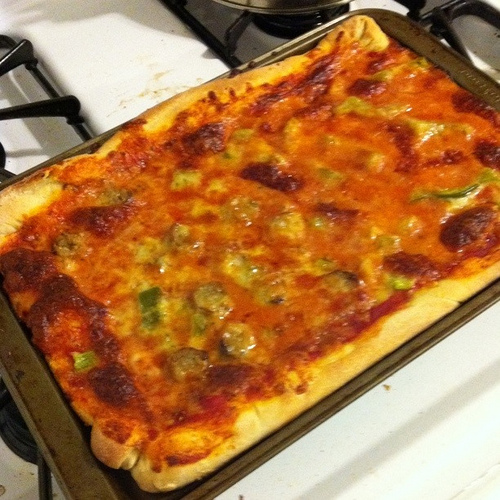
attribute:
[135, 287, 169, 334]
pepper — green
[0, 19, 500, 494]
pizza — big, rectangular, cheesy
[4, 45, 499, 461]
cheese — melted, crispy, bubbly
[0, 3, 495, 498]
pan — metal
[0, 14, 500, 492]
crust — well done, brown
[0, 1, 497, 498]
stove — dirty, white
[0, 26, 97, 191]
burner — black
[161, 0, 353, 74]
grate — black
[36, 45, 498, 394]
tomato sauce — red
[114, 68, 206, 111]
crumbs — brown